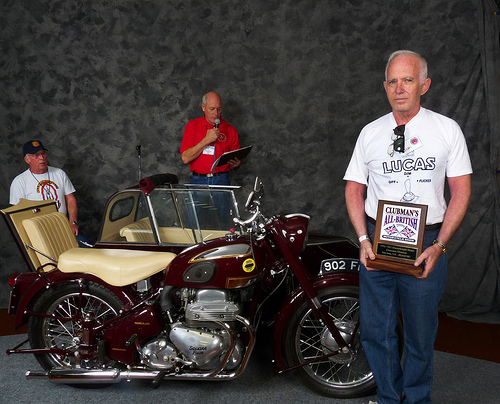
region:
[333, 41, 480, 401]
person with a white shirt standing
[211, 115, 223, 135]
microphone in a persons hand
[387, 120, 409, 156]
glasses hanging on a persons shirt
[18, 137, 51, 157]
hat on a persons head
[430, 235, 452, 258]
watch on a persons wrist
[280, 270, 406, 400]
front wheel on a motorcycle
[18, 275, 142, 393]
rear wheel on a motorcycle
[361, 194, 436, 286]
plaque in a persons hands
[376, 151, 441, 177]
lettering on a persons white shirt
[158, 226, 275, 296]
gas tank on a motorcycle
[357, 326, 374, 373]
part of a jeans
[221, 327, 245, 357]
part of a metal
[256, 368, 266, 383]
part of a floor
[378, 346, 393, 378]
part of a jeans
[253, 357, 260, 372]
part of a shade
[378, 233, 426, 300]
part of a board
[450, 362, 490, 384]
part of a floor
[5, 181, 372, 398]
a motorcycle and side car with a vintage appearance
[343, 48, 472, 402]
man standing with his legs close together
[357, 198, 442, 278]
man holding a plaque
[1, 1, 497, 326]
grey cloth wall in background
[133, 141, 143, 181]
the top of a microphone stand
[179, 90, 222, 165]
man holding a microphone to his mouth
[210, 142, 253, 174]
man holding a clipboard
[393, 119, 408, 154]
pair of dark sunglasses hung from man's collar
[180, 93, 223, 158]
man with microphone is wearing a rectangular tag on on his lower chest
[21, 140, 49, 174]
older man is wearing a dark baseball cap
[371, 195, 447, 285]
The man is holding a plaque.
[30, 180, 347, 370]
Motorcycle is on display.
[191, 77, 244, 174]
The man is talking on the microphone.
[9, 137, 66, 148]
The man is wearing a blue cap.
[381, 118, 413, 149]
The sunglasses on the shirt.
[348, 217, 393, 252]
Man is wearing a watch.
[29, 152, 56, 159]
The man is wearing eyeglasses.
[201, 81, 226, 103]
The man is bald on top.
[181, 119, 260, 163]
The man is wearing a red shirt.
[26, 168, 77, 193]
The man is wearing a necklace around neck.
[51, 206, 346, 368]
A motorcycle on the display.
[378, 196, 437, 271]
Man holding a plaque in hand.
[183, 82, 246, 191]
Old man talking on mike.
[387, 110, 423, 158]
Sunglasses on the man shirt.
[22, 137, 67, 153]
Man wearing a blue cap.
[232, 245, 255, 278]
Yellow sticker on the motorcycle.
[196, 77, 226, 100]
The man head is bald on top.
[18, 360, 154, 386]
The exhaust pipe on muffler is shiny.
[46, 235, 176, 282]
The seat of the motorcycle.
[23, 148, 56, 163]
The man is wearing glasses.